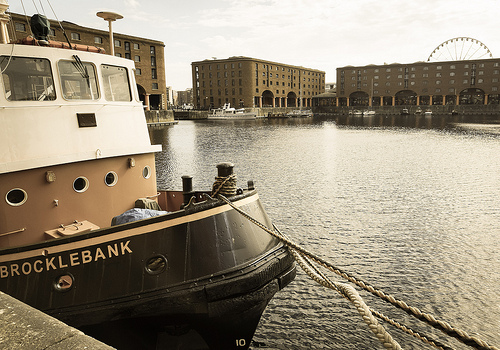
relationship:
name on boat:
[0, 242, 133, 281] [0, 14, 304, 344]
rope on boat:
[205, 169, 494, 350] [0, 14, 304, 344]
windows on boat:
[4, 54, 133, 103] [0, 14, 304, 344]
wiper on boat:
[71, 49, 94, 87] [0, 14, 304, 344]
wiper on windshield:
[71, 49, 94, 87] [60, 47, 108, 102]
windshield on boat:
[60, 47, 108, 102] [0, 14, 304, 344]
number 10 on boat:
[234, 336, 250, 349] [0, 14, 304, 344]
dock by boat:
[4, 291, 127, 350] [0, 14, 304, 344]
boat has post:
[0, 14, 304, 344] [219, 157, 238, 194]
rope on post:
[205, 169, 494, 350] [219, 157, 238, 194]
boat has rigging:
[0, 14, 304, 344] [10, 11, 126, 58]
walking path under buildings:
[251, 91, 298, 110] [195, 54, 496, 111]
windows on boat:
[4, 161, 165, 209] [0, 14, 304, 344]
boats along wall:
[280, 99, 464, 119] [246, 98, 500, 117]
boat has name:
[0, 14, 304, 344] [1, 243, 134, 281]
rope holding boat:
[205, 169, 494, 350] [0, 14, 304, 344]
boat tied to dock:
[0, 14, 304, 344] [4, 291, 127, 350]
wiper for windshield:
[71, 49, 94, 87] [60, 47, 108, 102]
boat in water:
[0, 14, 304, 344] [156, 110, 499, 347]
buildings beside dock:
[195, 54, 496, 111] [4, 291, 127, 350]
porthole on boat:
[7, 182, 32, 211] [0, 14, 304, 344]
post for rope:
[219, 157, 238, 194] [205, 169, 494, 350]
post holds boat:
[219, 157, 238, 194] [0, 14, 304, 344]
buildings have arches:
[195, 54, 496, 111] [352, 86, 484, 116]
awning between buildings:
[311, 87, 343, 111] [195, 54, 496, 111]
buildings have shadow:
[195, 54, 496, 111] [261, 106, 462, 127]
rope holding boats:
[205, 169, 494, 350] [280, 99, 464, 119]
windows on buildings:
[345, 61, 492, 84] [195, 54, 496, 111]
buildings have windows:
[195, 54, 496, 111] [4, 54, 133, 103]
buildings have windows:
[195, 54, 496, 111] [345, 61, 492, 84]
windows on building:
[345, 61, 492, 84] [339, 54, 500, 102]